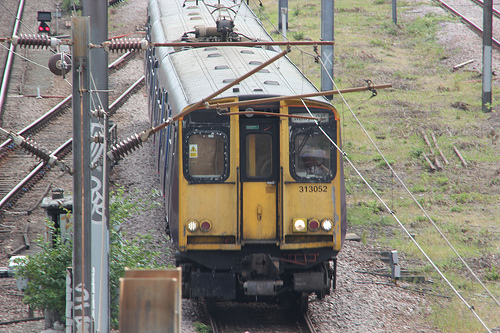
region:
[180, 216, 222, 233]
Front right signal light for train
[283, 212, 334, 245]
Front left signal light for train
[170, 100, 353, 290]
Front of yellow train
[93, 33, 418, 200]
Electrical installation hanging above train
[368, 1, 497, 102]
A grassy field next to train tracks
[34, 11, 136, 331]
A pole holding up an electrical installation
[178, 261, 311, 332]
The bottom front of a train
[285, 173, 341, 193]
The number 313052 on front of train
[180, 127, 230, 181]
A window on a train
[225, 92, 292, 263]
Back door of train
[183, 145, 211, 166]
Yellow tag in the window.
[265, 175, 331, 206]
The number of the train.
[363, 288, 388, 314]
Gravel next to the train.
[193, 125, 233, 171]
The window of the train.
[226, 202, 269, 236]
The train is yellow.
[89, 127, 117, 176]
Writing on the pole.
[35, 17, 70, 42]
Two red light on a pole.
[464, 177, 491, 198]
Dark patches of grass.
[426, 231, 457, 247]
The grass is green.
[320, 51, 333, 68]
An x on a pole.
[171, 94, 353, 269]
the train is yellow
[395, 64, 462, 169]
the grass is green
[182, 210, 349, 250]
the train has lights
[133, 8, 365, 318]
the train is stopped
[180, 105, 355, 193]
the train has windows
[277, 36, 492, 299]
the wires are gray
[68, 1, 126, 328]
the pole is gray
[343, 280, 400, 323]
the ground is brown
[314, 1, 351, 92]
the pole is standing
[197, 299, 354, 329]
the tracks are straight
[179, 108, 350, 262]
back of train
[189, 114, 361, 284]
yellow caboose of train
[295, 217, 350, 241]
lights on the back of train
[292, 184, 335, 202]
black numbers on the back of train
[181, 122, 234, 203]
windows framed in black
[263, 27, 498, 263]
cable lines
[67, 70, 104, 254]
graffiti on metal poles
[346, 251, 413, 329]
gravel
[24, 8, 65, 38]
two red lights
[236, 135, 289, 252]
yellow door on the back of train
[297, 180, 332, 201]
numbers on front of train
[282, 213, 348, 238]
lights on train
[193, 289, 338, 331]
railroad tracks for the train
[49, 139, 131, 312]
power lines to control power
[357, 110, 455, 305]
electrical power cords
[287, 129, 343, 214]
windows for person to control train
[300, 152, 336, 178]
conductor sitting inside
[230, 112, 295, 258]
door of the train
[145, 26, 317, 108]
top of the train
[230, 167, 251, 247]
handles to get out safely